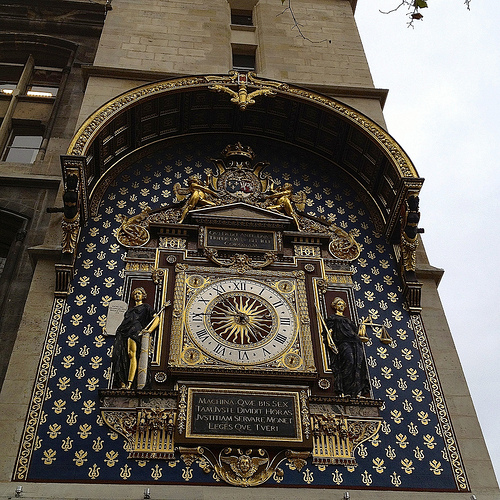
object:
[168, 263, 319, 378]
clock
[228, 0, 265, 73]
windows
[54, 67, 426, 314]
arch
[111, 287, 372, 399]
statues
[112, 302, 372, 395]
robes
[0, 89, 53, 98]
light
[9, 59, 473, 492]
design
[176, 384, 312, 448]
sign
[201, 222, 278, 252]
sign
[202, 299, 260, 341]
hands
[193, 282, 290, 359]
numerals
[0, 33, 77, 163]
window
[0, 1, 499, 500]
building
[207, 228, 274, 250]
black plaque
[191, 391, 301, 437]
black plaque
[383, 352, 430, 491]
background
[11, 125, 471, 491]
accents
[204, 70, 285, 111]
bird.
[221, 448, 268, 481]
figure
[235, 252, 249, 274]
humanhead figure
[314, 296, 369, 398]
figure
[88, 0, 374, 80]
wall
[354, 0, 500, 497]
sky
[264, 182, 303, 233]
statue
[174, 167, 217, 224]
statue